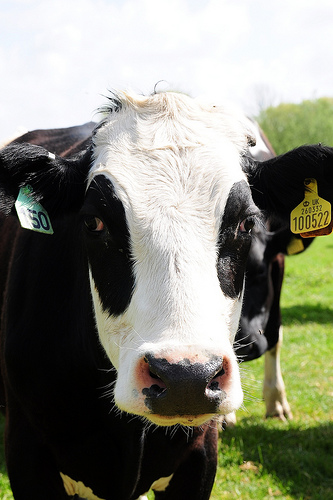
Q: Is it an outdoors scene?
A: Yes, it is outdoors.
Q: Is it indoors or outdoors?
A: It is outdoors.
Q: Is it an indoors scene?
A: No, it is outdoors.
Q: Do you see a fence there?
A: No, there are no fences.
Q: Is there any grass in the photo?
A: Yes, there is grass.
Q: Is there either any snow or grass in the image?
A: Yes, there is grass.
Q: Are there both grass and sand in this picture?
A: No, there is grass but no sand.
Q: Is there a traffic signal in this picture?
A: No, there are no traffic lights.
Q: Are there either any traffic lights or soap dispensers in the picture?
A: No, there are no traffic lights or soap dispensers.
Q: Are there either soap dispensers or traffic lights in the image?
A: No, there are no traffic lights or soap dispensers.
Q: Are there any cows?
A: Yes, there is a cow.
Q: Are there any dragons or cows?
A: Yes, there is a cow.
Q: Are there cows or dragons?
A: Yes, there is a cow.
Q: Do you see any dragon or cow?
A: Yes, there is a cow.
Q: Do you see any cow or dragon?
A: Yes, there is a cow.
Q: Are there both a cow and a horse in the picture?
A: No, there is a cow but no horses.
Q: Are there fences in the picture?
A: No, there are no fences.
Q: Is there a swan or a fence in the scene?
A: No, there are no fences or swans.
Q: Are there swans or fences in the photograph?
A: No, there are no fences or swans.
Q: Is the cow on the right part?
A: Yes, the cow is on the right of the image.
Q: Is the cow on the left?
A: No, the cow is on the right of the image.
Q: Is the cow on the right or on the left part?
A: The cow is on the right of the image.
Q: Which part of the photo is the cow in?
A: The cow is on the right of the image.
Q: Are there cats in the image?
A: No, there are no cats.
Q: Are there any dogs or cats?
A: No, there are no cats or dogs.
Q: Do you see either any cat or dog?
A: No, there are no cats or dogs.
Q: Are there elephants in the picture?
A: No, there are no elephants.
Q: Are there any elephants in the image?
A: No, there are no elephants.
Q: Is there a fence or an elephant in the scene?
A: No, there are no elephants or fences.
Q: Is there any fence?
A: No, there are no fences.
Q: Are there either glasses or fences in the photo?
A: No, there are no fences or glasses.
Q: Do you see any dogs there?
A: No, there are no dogs.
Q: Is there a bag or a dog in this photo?
A: No, there are no dogs or bags.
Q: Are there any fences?
A: No, there are no fences.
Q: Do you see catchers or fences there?
A: No, there are no fences or catchers.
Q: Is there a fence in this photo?
A: No, there are no fences.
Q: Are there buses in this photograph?
A: No, there are no buses.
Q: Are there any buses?
A: No, there are no buses.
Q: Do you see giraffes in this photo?
A: No, there are no giraffes.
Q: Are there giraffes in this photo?
A: No, there are no giraffes.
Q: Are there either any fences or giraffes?
A: No, there are no giraffes or fences.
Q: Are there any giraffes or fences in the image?
A: No, there are no giraffes or fences.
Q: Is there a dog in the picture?
A: No, there are no dogs.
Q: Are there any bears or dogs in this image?
A: No, there are no dogs or bears.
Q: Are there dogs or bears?
A: No, there are no dogs or bears.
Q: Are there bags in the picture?
A: No, there are no bags.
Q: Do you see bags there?
A: No, there are no bags.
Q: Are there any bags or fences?
A: No, there are no bags or fences.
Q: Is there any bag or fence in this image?
A: No, there are no bags or fences.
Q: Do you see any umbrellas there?
A: No, there are no umbrellas.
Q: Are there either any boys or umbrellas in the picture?
A: No, there are no umbrellas or boys.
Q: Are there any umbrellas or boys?
A: No, there are no umbrellas or boys.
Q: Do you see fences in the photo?
A: No, there are no fences.